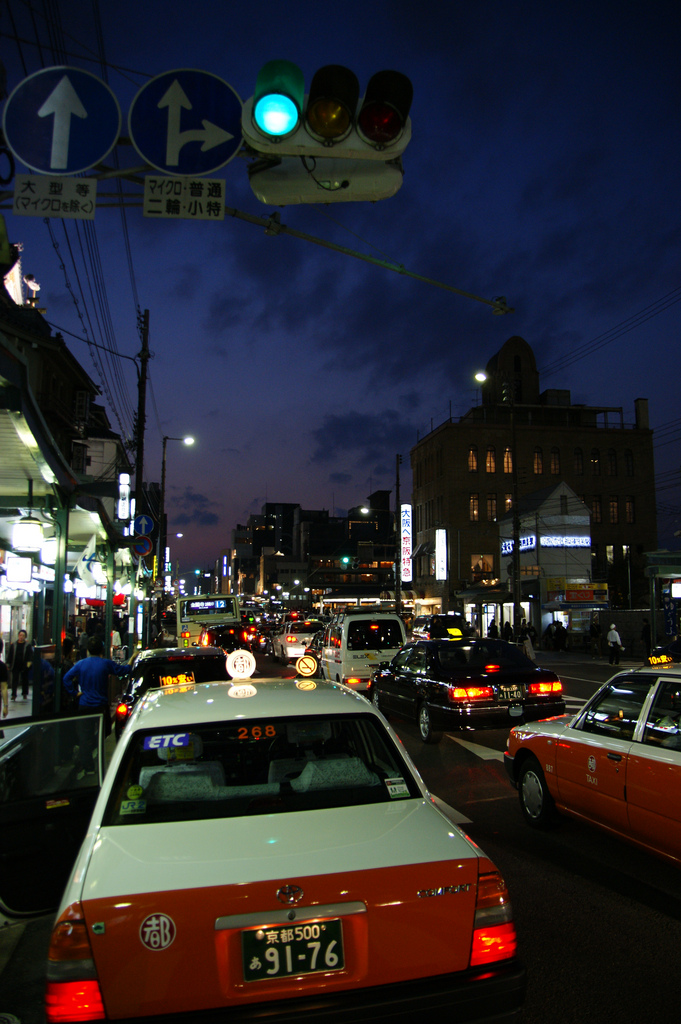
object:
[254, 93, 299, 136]
light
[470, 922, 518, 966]
tail light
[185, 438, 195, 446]
street light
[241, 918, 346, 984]
license plate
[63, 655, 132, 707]
top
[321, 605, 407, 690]
van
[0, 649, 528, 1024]
car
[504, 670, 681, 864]
car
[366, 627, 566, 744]
car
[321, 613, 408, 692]
car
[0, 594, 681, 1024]
street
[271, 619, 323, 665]
car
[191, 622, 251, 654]
car